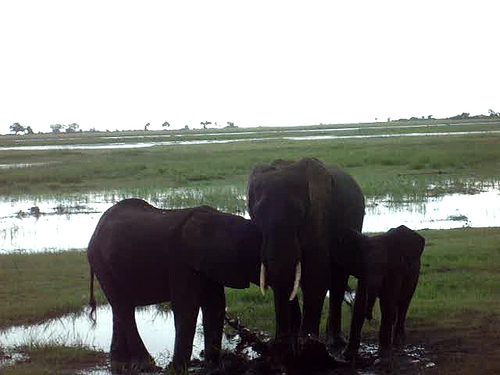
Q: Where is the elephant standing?
A: In a puddle.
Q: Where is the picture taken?
A: In the safari.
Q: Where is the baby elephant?
A: On the right.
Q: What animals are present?
A: Elephants.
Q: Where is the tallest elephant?
A: Middle.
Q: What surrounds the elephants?
A: Grass.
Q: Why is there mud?
A: Rain.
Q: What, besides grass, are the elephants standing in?
A: Water.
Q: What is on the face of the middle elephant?
A: Tusks.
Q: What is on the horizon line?
A: Trees.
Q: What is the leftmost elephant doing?
A: Nuzzling.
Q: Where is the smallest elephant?
A: On right.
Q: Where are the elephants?
A: Field.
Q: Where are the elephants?
A: By the water.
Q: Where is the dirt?
A: Next to the water.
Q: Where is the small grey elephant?
A: Next to the big elephant.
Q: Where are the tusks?
A: On the elephant.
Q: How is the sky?
A: Hazy and white.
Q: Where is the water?
A: Behind the elephants.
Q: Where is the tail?
A: On the elephant.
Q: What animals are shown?
A: Elephants.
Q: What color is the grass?
A: Green.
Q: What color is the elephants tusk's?
A: White.